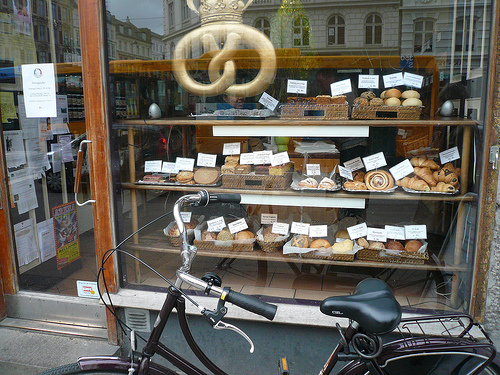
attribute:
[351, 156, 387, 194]
rolls — cinnamon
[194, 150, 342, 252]
goods — baked goods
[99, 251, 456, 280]
tile floor — brown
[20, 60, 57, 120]
paper — white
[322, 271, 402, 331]
seat — black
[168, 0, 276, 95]
display — giant, golden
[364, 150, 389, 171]
paper — white